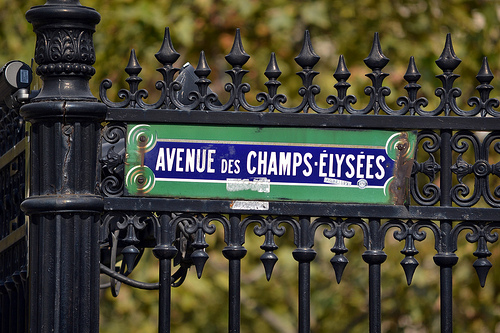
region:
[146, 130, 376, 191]
the sign says avenue des champs elysees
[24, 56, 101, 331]
pole of the fence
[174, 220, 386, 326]
gate of the fence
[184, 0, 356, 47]
plants are behind fence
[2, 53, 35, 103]
mirror on side of gate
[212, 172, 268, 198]
tape on the sign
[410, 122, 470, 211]
ornate pattern of fence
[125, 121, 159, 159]
circle pattern on sign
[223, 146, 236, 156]
blue part of sign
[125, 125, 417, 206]
Green, blue and white street sign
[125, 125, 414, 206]
Green, blue and white street sign on metal fence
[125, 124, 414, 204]
Green, blue and white street sign is burnt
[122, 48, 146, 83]
Black metal spike on black metal gate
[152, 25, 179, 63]
Black metal spike on black metal gate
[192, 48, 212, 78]
Black metal spike on black metal gate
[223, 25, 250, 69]
Black metal spike on black metal gate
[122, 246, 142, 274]
Black metal spike on black metal gate is pointing down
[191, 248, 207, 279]
Black metal spike on black metal gate is below street sign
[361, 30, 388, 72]
Black metal spike on black metal gate is above street sign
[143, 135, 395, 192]
white letters on blue background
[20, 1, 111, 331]
a black pole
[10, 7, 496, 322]
the fence is black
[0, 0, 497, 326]
the fence is metal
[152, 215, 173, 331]
banister of a fence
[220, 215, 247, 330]
banister of a fence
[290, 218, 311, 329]
banister of a fence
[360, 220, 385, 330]
banister of a fence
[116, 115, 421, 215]
a green sign on a fence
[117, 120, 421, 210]
sign has white letters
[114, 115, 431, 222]
green, blue and white street sign on metal fence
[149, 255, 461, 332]
black metal spoke on metal fence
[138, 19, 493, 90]
triangular spikes on top of black metal fence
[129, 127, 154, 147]
bolt on face of street sign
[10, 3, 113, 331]
metal fence support pole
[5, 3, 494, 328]
green foliage behind metal fence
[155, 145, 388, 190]
white letters on face of blue sign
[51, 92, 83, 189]
crack in metal fence support pole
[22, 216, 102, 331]
ridges in black metal support pole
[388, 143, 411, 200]
brown rust on face of street sign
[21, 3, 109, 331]
A corner pole of an iron fence.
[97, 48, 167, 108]
A decorative part of a fence.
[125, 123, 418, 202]
A rusting street sign.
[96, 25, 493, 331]
A decorative iron fence.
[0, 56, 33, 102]
A newer piece of an iron fence.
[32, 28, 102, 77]
Nice decoration of an old fence post.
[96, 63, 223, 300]
Old fence with newer camera on the inside.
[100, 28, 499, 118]
Decoration and security on an iron fence.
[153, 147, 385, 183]
French street sign, Avenue des Champs-Elysees.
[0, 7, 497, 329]
Corner of an iron fence with a street sign mounted.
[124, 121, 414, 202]
A sign on a fence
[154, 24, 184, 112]
A spike on a gate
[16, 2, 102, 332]
A post on a gate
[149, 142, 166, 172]
a letter on a sign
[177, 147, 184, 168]
a letter on a sign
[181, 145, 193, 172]
a letter on a sign